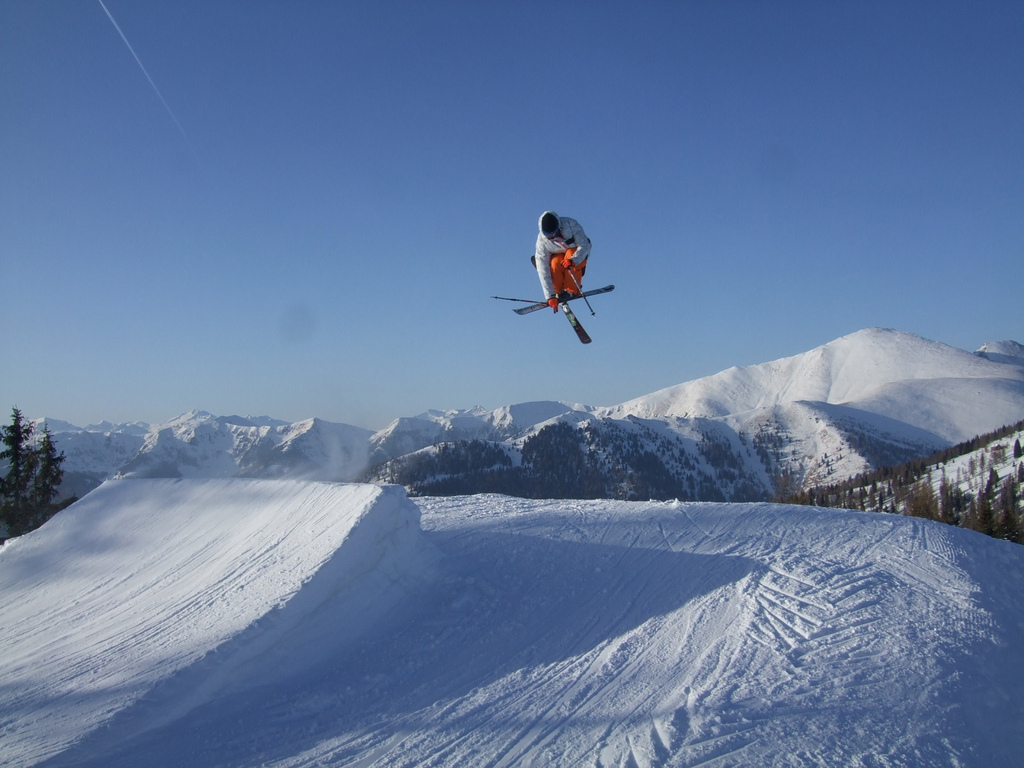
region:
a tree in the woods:
[7, 409, 28, 543]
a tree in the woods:
[28, 414, 66, 522]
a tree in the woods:
[999, 471, 1018, 544]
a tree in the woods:
[958, 485, 990, 525]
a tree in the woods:
[929, 469, 958, 527]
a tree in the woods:
[917, 477, 940, 522]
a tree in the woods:
[865, 475, 882, 498]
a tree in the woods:
[843, 480, 859, 509]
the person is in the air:
[393, 160, 682, 411]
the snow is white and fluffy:
[387, 406, 852, 732]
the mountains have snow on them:
[29, 272, 978, 484]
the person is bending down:
[452, 156, 630, 324]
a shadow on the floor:
[282, 446, 770, 712]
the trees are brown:
[772, 440, 1001, 538]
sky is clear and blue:
[2, 1, 1021, 423]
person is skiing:
[492, 205, 616, 346]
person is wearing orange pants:
[494, 207, 616, 354]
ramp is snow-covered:
[1, 466, 458, 765]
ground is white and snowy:
[1, 323, 1022, 767]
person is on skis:
[488, 207, 615, 348]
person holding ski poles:
[488, 215, 624, 351]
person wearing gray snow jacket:
[491, 203, 621, 352]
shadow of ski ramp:
[0, 468, 1021, 766]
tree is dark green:
[5, 406, 72, 553]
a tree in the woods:
[7, 404, 24, 523]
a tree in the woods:
[828, 490, 842, 511]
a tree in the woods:
[835, 484, 846, 507]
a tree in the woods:
[938, 477, 955, 534]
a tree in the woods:
[993, 466, 1022, 537]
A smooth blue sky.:
[1, 4, 1020, 406]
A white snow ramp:
[1, 475, 416, 764]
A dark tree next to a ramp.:
[1, 409, 68, 537]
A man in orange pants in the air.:
[532, 209, 591, 305]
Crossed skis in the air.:
[513, 257, 612, 347]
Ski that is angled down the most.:
[532, 254, 594, 347]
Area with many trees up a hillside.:
[775, 421, 1022, 551]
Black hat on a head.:
[538, 213, 561, 239]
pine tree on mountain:
[853, 480, 870, 499]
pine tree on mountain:
[877, 486, 887, 506]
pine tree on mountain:
[902, 467, 919, 494]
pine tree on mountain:
[905, 479, 932, 524]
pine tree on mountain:
[995, 497, 1014, 527]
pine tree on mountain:
[465, 448, 486, 478]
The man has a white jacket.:
[500, 176, 615, 367]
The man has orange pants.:
[531, 252, 604, 317]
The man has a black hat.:
[522, 205, 577, 248]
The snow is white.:
[81, 500, 214, 599]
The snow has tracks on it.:
[547, 541, 827, 715]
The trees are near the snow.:
[0, 380, 89, 545]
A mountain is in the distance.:
[808, 288, 927, 466]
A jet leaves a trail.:
[61, 0, 195, 165]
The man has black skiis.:
[495, 285, 626, 340]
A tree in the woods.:
[31, 427, 82, 538]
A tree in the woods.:
[0, 416, 54, 547]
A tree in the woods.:
[903, 479, 924, 519]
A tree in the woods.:
[932, 478, 949, 517]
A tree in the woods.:
[944, 479, 967, 534]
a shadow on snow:
[190, 464, 804, 766]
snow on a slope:
[32, 445, 883, 766]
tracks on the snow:
[623, 519, 909, 750]